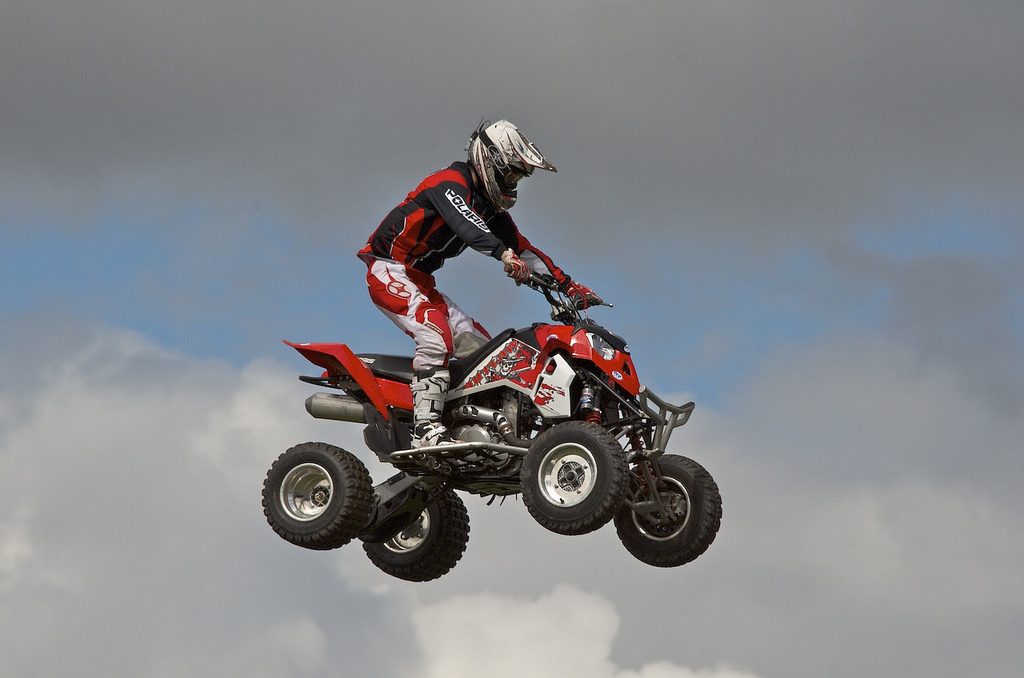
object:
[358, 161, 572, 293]
jacket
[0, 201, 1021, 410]
sky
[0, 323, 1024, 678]
clouds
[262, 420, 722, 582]
four wheeler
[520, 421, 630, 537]
tire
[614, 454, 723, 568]
tire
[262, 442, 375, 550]
tire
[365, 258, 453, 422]
leg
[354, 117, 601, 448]
man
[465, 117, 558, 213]
helmet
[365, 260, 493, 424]
pants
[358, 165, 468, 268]
red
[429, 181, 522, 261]
black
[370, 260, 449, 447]
white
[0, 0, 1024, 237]
clouds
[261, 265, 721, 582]
object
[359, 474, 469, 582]
wheel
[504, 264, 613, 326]
handlebars